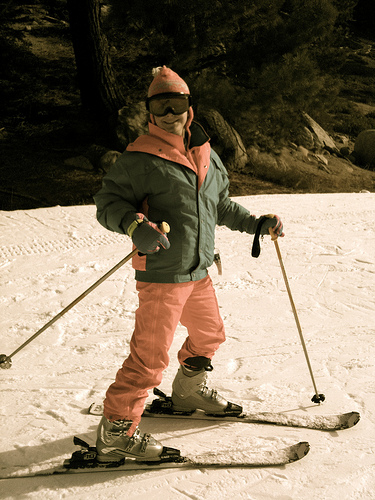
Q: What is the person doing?
A: Sking.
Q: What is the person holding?
A: Ski poles.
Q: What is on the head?
A: Hat.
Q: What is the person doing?
A: Sking.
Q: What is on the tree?
A: Green leaves.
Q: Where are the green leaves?
A: On the tree.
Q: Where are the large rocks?
A: On the ground.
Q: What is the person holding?
A: Ski poles.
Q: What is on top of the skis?
A: Snow.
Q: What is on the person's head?
A: Hat.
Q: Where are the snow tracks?
A: Snow.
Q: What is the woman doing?
A: Posing.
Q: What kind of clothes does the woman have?
A: Warm clothes.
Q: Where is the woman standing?
A: In the snow.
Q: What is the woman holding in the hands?
A: Ski poles.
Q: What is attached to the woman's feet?
A: Skis.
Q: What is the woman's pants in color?
A: Pink.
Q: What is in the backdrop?
A: Trees and rocks.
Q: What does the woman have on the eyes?
A: Ski goggles.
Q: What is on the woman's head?
A: Winter cap.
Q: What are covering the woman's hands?
A: Gloves.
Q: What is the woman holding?
A: Ski poles.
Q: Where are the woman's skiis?
A: On her feet.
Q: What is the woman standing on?
A: Snow.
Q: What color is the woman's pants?
A: Pink.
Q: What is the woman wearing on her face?
A: Snow goggles.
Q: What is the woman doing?
A: Skiing.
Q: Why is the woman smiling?
A: She's having fun.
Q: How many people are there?
A: One.